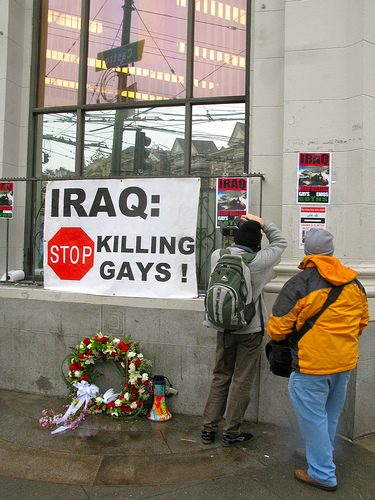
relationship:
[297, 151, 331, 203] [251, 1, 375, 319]
paper hanging on wall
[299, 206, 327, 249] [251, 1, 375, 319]
paper hanging on wall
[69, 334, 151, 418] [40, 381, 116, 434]
wreath has ribbon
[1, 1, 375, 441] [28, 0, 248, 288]
building has window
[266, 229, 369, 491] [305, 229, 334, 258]
person wearing hat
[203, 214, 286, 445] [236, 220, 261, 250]
person wearing hat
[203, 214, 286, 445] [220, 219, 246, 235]
person holding camera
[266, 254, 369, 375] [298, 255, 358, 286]
jacket has hood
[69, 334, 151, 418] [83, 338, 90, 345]
wreath has flower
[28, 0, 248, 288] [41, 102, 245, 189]
window has relection of house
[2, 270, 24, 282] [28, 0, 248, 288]
paper towel next to window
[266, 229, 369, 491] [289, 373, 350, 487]
person wearing pants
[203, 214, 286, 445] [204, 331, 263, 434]
person wearing pants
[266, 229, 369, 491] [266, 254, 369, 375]
person wearing jacket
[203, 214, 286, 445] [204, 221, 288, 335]
person wearing shirt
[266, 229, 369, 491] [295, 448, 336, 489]
person wearing shoes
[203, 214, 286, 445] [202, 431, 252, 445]
person wearing shoes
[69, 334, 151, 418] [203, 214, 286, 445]
wreath next to person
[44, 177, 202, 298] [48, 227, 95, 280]
board has symbol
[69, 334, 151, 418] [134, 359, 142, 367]
wreath has flower